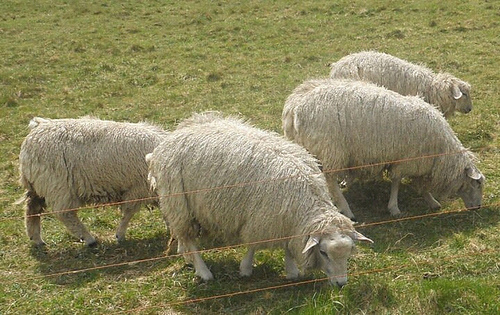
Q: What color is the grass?
A: Green.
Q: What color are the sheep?
A: White.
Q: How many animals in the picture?
A: Four.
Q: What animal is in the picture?
A: Sheep.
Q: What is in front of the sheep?
A: Fence.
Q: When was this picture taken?
A: Daytime.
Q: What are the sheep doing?
A: Eating.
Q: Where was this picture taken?
A: At a farm.